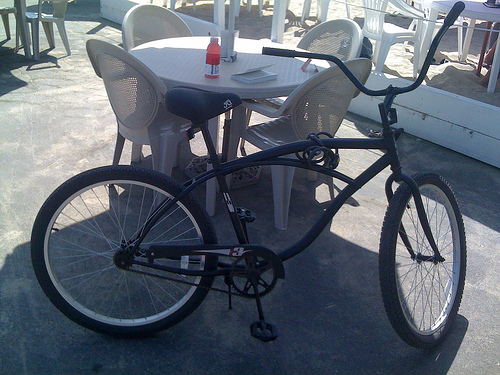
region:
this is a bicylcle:
[34, 7, 473, 354]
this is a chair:
[82, 34, 185, 165]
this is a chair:
[244, 55, 374, 224]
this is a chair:
[124, 8, 184, 43]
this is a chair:
[359, 2, 424, 77]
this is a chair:
[31, 2, 74, 60]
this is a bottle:
[197, 32, 224, 78]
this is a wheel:
[367, 175, 472, 360]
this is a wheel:
[28, 170, 223, 337]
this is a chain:
[114, 240, 268, 293]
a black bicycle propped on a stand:
[29, 2, 466, 350]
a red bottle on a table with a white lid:
[206, 34, 222, 80]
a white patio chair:
[83, 37, 219, 214]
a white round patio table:
[127, 33, 330, 189]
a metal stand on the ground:
[188, 153, 265, 184]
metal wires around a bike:
[296, 131, 339, 168]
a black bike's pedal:
[251, 318, 278, 341]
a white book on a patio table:
[232, 64, 275, 86]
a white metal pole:
[226, 0, 237, 58]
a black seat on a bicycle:
[166, 88, 241, 120]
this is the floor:
[42, 98, 69, 126]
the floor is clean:
[319, 294, 359, 350]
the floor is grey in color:
[310, 291, 346, 345]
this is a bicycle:
[34, 77, 494, 336]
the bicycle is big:
[29, 18, 463, 350]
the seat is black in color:
[178, 88, 194, 100]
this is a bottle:
[205, 39, 222, 83]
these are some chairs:
[62, 4, 362, 144]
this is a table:
[156, 41, 181, 66]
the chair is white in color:
[108, 82, 130, 114]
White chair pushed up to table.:
[57, 23, 155, 130]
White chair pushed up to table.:
[283, 75, 373, 167]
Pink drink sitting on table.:
[200, 50, 226, 80]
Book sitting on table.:
[234, 59, 288, 97]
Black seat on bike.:
[176, 78, 293, 146]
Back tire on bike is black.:
[38, 173, 212, 359]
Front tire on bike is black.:
[386, 182, 479, 312]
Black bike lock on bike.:
[300, 125, 346, 177]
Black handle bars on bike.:
[283, 43, 461, 88]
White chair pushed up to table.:
[110, 9, 203, 39]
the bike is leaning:
[16, 51, 477, 371]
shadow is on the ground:
[280, 274, 360, 371]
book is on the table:
[228, 48, 275, 89]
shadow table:
[151, 45, 306, 90]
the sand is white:
[445, 65, 474, 93]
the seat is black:
[166, 83, 243, 119]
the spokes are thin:
[83, 210, 106, 286]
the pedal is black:
[242, 317, 284, 345]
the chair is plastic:
[21, 6, 76, 62]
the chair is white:
[28, 7, 78, 56]